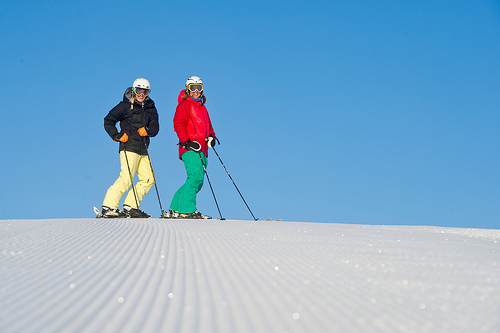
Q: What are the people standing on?
A: Snow.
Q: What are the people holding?
A: Ski poles.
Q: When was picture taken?
A: Day time.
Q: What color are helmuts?
A: White.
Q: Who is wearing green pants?
A: Person on right.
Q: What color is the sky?
A: Blue.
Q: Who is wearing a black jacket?
A: Skier on left.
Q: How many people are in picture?
A: Two.